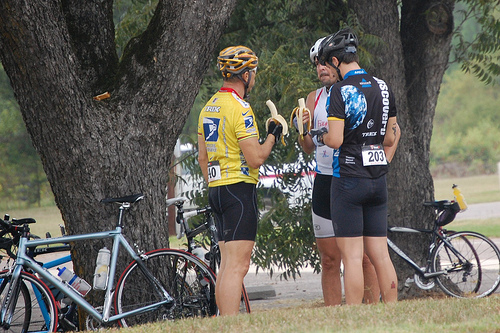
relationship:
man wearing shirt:
[198, 43, 283, 318] [195, 90, 259, 187]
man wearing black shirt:
[312, 27, 398, 305] [327, 68, 397, 178]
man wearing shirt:
[312, 27, 398, 305] [308, 84, 344, 176]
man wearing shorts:
[312, 27, 398, 305] [308, 171, 339, 243]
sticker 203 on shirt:
[358, 144, 403, 177] [322, 71, 407, 178]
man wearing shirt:
[312, 44, 417, 314] [322, 71, 407, 178]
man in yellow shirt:
[198, 43, 283, 318] [196, 87, 261, 186]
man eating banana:
[198, 43, 283, 318] [262, 97, 289, 138]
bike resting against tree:
[353, 191, 498, 300] [337, 0, 467, 290]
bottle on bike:
[449, 182, 471, 210] [6, 187, 208, 331]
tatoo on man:
[387, 278, 397, 290] [317, 25, 397, 305]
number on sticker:
[368, 153, 388, 167] [202, 164, 218, 178]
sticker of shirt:
[202, 164, 218, 178] [188, 82, 269, 191]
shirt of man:
[188, 82, 269, 191] [189, 39, 272, 324]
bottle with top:
[56, 265, 90, 295] [53, 265, 66, 275]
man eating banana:
[198, 44, 283, 316] [257, 86, 299, 163]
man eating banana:
[312, 27, 398, 305] [287, 87, 315, 144]